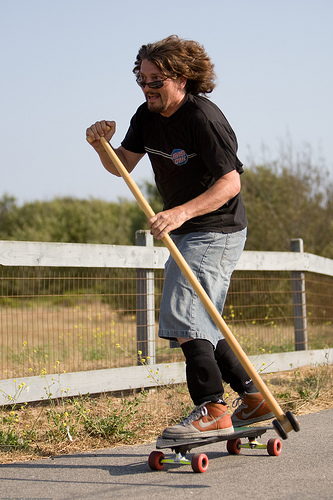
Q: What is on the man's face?
A: Sunglasses.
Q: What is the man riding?
A: A skateboard.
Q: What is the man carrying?
A: A wooden mallet.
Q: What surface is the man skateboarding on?
A: Pavement.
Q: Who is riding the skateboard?
A: A man with long hair.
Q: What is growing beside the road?
A: Weeds.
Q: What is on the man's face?
A: Sunglasses.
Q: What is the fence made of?
A: Wood and metal.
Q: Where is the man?
A: On the skateboard.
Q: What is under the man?
A: A skateboard.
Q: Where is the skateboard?
A: Under the man.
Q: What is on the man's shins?
A: Shin guards.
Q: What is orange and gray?
A: The man's shoes.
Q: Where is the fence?
A: On the grass.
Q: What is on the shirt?
A: A band logo.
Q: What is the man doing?
A: Skateboarding.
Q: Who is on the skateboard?
A: A man.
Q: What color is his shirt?
A: Black.